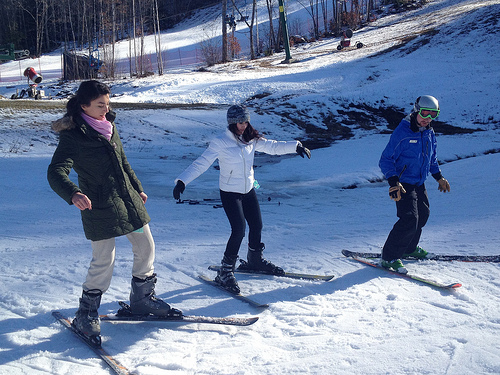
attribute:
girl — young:
[209, 87, 307, 255]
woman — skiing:
[15, 16, 149, 277]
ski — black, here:
[113, 272, 345, 317]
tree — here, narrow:
[29, 8, 238, 92]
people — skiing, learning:
[15, 31, 479, 312]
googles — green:
[392, 84, 458, 134]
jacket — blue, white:
[384, 116, 438, 203]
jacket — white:
[209, 130, 270, 219]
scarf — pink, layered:
[83, 102, 131, 150]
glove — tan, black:
[298, 125, 334, 194]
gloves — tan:
[386, 179, 459, 203]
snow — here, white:
[290, 164, 340, 283]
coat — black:
[53, 110, 159, 225]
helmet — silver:
[411, 80, 444, 120]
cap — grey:
[220, 96, 260, 135]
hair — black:
[247, 124, 262, 152]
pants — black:
[213, 185, 315, 299]